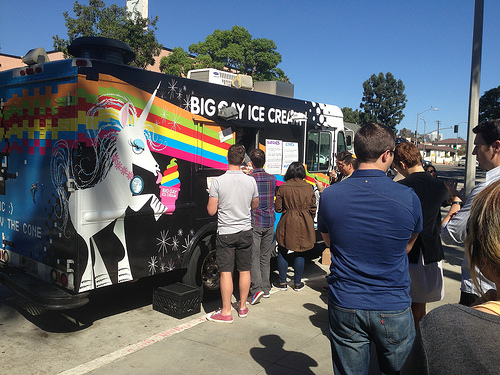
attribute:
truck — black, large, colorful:
[5, 43, 344, 337]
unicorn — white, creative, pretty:
[62, 76, 165, 290]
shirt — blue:
[318, 175, 420, 311]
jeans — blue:
[321, 301, 419, 372]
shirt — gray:
[211, 169, 256, 234]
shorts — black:
[218, 229, 257, 277]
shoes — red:
[210, 307, 257, 326]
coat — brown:
[275, 178, 317, 249]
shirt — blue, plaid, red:
[254, 169, 279, 231]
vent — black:
[69, 35, 140, 65]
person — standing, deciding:
[208, 140, 251, 331]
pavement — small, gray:
[6, 277, 333, 371]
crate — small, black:
[150, 282, 207, 321]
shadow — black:
[248, 301, 334, 372]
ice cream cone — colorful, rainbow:
[157, 159, 184, 211]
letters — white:
[187, 92, 308, 130]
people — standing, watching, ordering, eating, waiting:
[214, 82, 500, 369]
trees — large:
[50, 5, 281, 80]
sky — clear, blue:
[6, 6, 495, 84]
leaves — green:
[205, 42, 254, 59]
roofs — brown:
[410, 134, 464, 154]